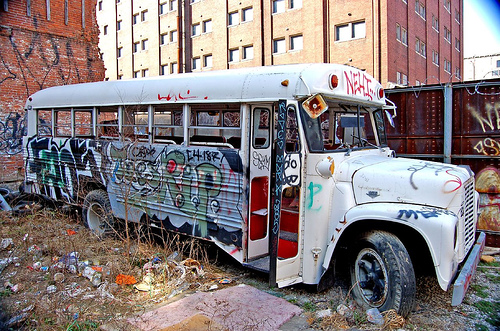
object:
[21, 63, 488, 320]
bus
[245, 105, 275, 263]
door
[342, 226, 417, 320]
tire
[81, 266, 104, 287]
trash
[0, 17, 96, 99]
graffiti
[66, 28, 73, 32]
brick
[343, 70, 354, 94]
letter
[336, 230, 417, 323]
wheel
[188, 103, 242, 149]
window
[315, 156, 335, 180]
headlight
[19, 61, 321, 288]
side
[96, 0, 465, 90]
building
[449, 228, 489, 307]
bumper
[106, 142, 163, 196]
word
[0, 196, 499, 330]
ground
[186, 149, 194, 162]
letter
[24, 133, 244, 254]
graffiti